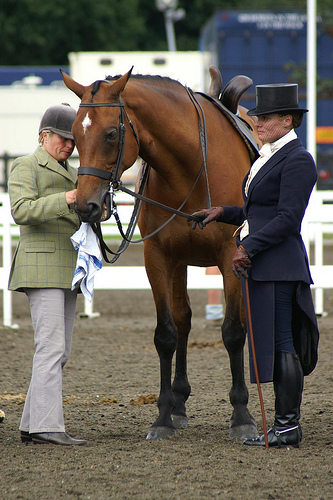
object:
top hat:
[246, 83, 309, 116]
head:
[251, 112, 303, 138]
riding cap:
[39, 102, 77, 143]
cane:
[243, 266, 271, 446]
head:
[56, 67, 140, 222]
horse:
[62, 71, 270, 449]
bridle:
[75, 80, 214, 262]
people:
[7, 85, 318, 447]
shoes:
[246, 347, 304, 446]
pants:
[19, 287, 77, 436]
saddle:
[221, 70, 263, 148]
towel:
[72, 219, 105, 319]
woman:
[192, 82, 320, 444]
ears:
[59, 67, 133, 95]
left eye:
[106, 127, 119, 142]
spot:
[81, 112, 92, 135]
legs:
[144, 239, 257, 443]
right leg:
[144, 246, 179, 444]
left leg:
[223, 239, 262, 441]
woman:
[4, 102, 85, 446]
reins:
[86, 88, 212, 263]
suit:
[221, 129, 321, 382]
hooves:
[146, 413, 263, 441]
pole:
[305, 1, 317, 196]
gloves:
[190, 206, 252, 281]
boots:
[19, 431, 86, 446]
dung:
[102, 393, 156, 408]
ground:
[0, 237, 331, 498]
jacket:
[7, 145, 78, 291]